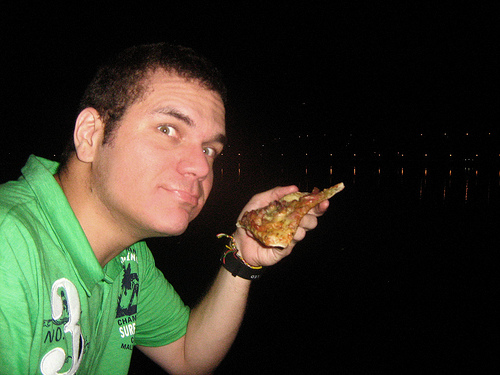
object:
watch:
[210, 233, 267, 282]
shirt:
[0, 155, 188, 375]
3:
[37, 275, 84, 374]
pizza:
[237, 181, 347, 248]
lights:
[448, 154, 452, 157]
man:
[5, 47, 345, 374]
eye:
[154, 123, 186, 143]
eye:
[201, 142, 222, 162]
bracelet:
[209, 232, 270, 281]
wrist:
[214, 235, 266, 285]